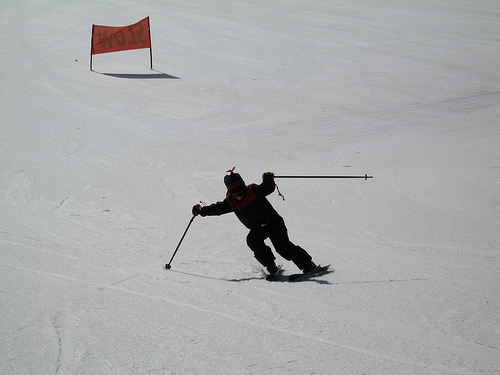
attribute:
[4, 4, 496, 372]
snow — white, packed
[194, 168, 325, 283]
skier — wearing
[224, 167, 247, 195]
hat — knitted, knit, black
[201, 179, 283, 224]
sweater — red, black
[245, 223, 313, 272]
pants — black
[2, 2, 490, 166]
slope — well groomed, snow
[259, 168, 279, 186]
glove — black